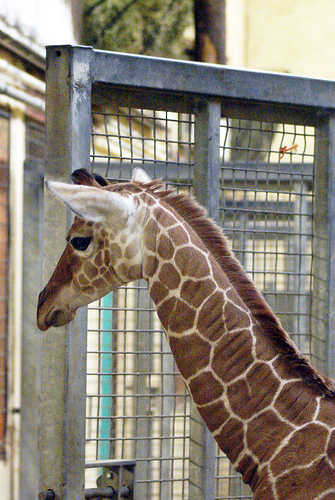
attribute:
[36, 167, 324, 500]
giraffe — patterned, brown, furry, here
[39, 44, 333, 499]
gate — metal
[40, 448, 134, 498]
lock — silver, metal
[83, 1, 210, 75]
trees — green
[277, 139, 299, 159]
string — knotted, orange, red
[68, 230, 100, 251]
eye — here, black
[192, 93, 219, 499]
bar — metal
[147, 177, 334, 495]
neck — wrinkled